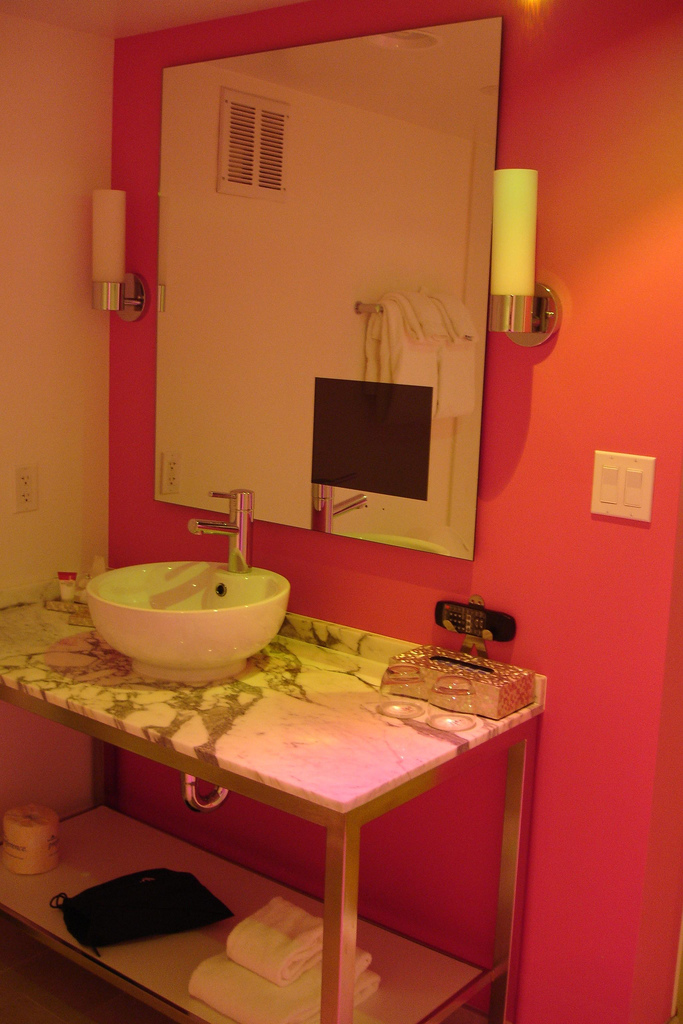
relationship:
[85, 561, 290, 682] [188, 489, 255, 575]
bowl with faucet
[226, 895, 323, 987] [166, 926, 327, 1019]
towel in a stack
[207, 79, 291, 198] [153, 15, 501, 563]
air vent on mirror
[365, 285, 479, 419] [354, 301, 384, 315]
hand towels on rail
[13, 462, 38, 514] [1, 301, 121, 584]
outlet on wall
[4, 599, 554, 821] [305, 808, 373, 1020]
counter has leg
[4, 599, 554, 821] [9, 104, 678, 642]
counter in bathroom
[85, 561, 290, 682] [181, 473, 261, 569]
bowl has faucet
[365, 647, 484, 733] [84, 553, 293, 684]
glasses on sink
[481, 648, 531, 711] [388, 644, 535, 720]
flower design on flower design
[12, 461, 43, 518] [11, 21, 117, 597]
outlet on the wall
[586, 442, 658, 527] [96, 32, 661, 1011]
light switch on the wall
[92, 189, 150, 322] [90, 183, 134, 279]
fixture with a globe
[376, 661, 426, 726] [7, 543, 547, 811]
glass on counter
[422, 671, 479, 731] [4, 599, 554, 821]
glass on counter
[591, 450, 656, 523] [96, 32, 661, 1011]
light switch on the wall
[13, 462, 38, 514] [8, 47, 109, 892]
outlet on the wall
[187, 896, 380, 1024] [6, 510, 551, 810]
stack under  the counter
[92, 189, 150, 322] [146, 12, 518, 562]
fixture next to the mirror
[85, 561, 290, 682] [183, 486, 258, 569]
bowl with faucet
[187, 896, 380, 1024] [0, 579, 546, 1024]
stack on the bottom of counter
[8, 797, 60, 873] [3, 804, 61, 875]
roll of roll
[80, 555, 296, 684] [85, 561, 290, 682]
bowl as the bowl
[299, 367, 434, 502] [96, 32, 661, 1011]
mirror on the side of the wall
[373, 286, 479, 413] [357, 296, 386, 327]
hand towels on the rail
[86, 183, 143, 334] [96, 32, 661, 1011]
fixture on the wall